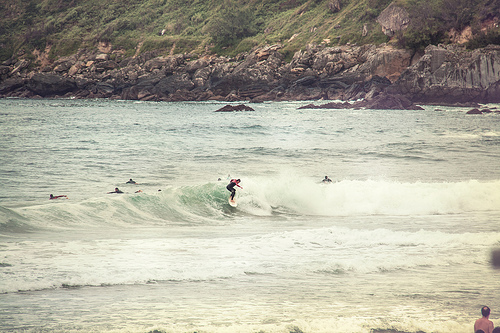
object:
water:
[1, 232, 498, 333]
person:
[126, 179, 137, 185]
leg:
[134, 190, 142, 193]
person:
[105, 187, 142, 194]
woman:
[494, 326, 499, 332]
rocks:
[0, 43, 113, 91]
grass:
[2, 0, 123, 48]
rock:
[214, 105, 253, 112]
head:
[129, 178, 133, 181]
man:
[226, 179, 242, 202]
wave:
[262, 179, 498, 232]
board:
[228, 197, 238, 207]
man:
[474, 307, 494, 333]